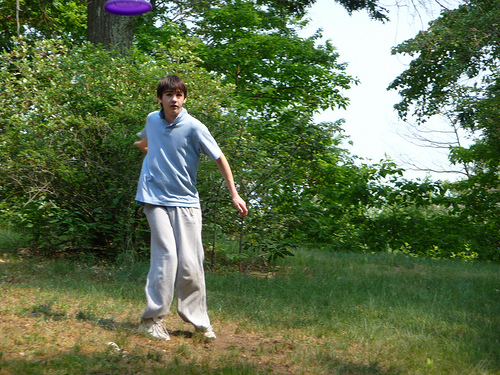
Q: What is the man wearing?
A: Clothes.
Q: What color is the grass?
A: Green.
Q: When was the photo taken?
A: Daytime.